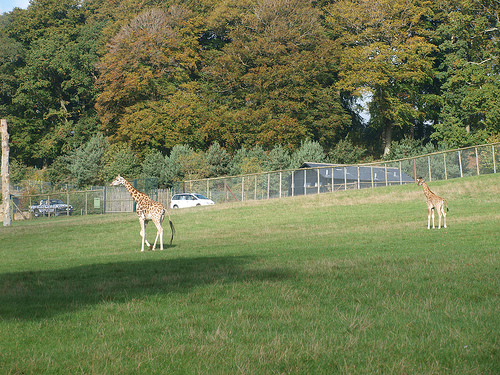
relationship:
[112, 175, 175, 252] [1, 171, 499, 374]
giraffe in field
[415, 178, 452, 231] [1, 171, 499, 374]
giraffe in field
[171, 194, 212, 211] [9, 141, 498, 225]
car in front of fence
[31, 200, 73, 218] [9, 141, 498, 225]
truck behind fence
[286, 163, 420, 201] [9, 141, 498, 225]
building behind fence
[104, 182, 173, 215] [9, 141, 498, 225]
fence gates are part of fence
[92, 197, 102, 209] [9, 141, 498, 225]
sign on fence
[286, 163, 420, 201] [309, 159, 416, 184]
building has roof